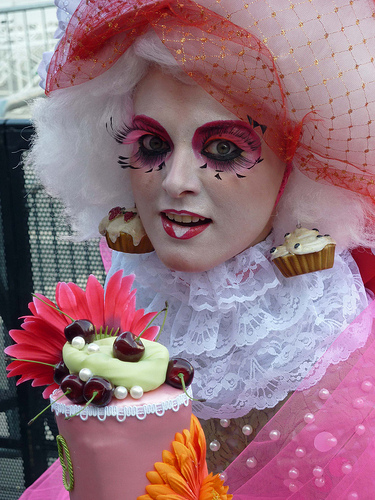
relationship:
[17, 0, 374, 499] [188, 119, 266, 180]
lady in make-up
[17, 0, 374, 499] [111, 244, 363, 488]
lady in costume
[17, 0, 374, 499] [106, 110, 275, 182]
lady with eyelashes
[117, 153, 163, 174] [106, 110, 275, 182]
feathers on eyelashes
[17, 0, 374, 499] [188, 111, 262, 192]
lady with make-up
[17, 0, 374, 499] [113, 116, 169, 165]
lady with lashes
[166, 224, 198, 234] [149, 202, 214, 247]
lipstick on lips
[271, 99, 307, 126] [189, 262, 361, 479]
ground on dress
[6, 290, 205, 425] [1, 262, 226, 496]
cherries and flowers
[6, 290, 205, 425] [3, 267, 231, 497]
cherries on costume piece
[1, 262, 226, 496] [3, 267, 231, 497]
flowers on costume piece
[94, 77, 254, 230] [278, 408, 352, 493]
beads on chiffon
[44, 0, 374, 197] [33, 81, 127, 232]
net on wig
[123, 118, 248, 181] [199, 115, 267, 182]
eyes with lashes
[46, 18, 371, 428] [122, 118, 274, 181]
lady has eyelashes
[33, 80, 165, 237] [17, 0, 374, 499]
hair of lady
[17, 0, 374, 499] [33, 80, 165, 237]
lady has hair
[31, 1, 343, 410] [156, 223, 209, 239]
lady has lips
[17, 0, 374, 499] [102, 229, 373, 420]
lady has collar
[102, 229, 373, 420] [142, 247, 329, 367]
collar around neck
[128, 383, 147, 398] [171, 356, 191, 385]
pearl near cherry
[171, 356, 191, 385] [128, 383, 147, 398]
cherry near pearl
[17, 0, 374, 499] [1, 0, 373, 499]
lady wearing costume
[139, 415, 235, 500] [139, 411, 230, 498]
flower of flower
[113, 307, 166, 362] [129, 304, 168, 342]
cherry with stem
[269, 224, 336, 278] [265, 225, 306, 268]
cupcake with frosting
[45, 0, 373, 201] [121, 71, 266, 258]
net on head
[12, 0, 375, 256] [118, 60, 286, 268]
hair on head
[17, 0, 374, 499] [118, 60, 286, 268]
lady has head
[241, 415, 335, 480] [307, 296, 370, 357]
veil around shoulder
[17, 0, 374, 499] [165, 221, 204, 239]
lady with lipstick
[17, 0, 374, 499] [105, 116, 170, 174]
lady with lashes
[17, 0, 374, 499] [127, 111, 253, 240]
lady wearing makeup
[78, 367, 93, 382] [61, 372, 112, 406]
pearl above cherries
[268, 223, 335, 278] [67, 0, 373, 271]
cupcake on woman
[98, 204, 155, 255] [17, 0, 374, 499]
earring on lady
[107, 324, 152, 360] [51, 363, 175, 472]
cherry on top of dish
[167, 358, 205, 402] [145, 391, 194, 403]
cherry on surface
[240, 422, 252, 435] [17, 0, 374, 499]
white pearl on lady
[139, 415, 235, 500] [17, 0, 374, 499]
flower on lady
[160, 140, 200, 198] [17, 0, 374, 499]
nose on lady